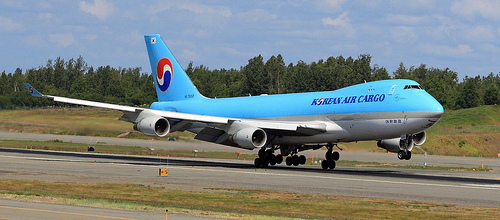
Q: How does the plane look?
A: Big.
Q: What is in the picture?
A: Blue and gray plane.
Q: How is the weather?
A: Cloudy.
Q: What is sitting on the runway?
A: The airplane.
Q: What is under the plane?
A: The landing gear.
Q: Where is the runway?
A: Under the plane.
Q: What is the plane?
A: Blue and white vehicle.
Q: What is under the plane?
A: The plane's shadow.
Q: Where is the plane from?
A: Korean Air Cargo.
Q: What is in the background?
A: Trees.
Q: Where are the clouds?
A: In the sky.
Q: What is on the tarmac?
A: A plane.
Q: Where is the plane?
A: On a runway.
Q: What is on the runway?
A: A blue plane.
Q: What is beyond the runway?
A: A line of trees.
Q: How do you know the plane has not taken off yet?
A: The wheels are on the ground.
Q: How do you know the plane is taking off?
A: The front tire has left the ground.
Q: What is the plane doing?
A: Prepairing to take off.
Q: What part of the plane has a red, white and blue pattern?
A: On the tail.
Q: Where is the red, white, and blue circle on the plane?
A: On the tail.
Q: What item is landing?
A: Plane.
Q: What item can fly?
A: Plane.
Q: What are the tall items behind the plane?
A: Trees.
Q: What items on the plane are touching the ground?
A: Wheels.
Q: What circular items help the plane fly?
A: Engines.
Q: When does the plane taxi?
A: Before takeoff.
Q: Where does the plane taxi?
A: Runway.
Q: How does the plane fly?
A: Engines.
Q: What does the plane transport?
A: Passengers.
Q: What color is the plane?
A: Light blue.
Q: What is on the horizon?
A: Trees.